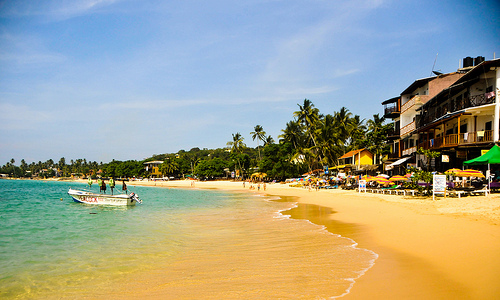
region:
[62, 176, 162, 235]
white boat in water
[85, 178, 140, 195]
people near boat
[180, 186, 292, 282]
water coming up to sand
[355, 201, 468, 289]
sand is bright orange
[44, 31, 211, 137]
sky is blue with few clouds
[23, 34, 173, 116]
clouds are white and thin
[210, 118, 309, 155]
tall palm trees in distance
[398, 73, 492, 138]
large building on right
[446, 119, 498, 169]
green umbrella under building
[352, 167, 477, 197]
numerous red and yellow umbrellas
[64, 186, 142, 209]
a white boat on the water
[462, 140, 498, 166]
a green umbrella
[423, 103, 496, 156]
a balcony on a house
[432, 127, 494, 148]
a railing on a balcony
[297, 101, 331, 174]
a palm tree leaning toward the water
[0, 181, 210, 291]
beautiful blue water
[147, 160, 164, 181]
a yellow house in the trees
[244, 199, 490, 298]
a strip of brown sand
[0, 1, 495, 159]
a bright blue and white sky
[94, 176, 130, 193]
people in the water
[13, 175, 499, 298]
the sand is yellow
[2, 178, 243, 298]
the ocean is blue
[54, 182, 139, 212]
the boat is white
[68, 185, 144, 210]
this is a boat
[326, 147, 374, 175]
the house is yellow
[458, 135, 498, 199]
the umbrella is green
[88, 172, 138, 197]
the people are on the boat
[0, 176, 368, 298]
the water is calm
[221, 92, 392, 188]
the palm trees are tall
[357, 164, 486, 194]
the umbrellas are yellow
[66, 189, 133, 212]
a little boat in the water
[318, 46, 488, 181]
the houses on the beach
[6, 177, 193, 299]
the lovely water of the ocean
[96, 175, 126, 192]
the people on the boat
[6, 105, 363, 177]
the trees in a line along the beach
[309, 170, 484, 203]
people sitting underneath umbrellas by the buildings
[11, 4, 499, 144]
the blue sky above with some white clouds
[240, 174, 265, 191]
some people standing on the beach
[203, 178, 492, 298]
the clean beach next to the water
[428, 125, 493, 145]
the balcony of the people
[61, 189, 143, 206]
a motor boat on the water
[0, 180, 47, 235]
turquoise transparent ocean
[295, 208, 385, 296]
a gentle ocean wave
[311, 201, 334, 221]
wet sand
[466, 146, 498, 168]
a bright green canopy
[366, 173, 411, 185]
yellow and orange umbrellas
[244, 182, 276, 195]
people on the beach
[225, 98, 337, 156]
palm trees on the beach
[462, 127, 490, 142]
towels hanging from a balcony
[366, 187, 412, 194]
a small white fence